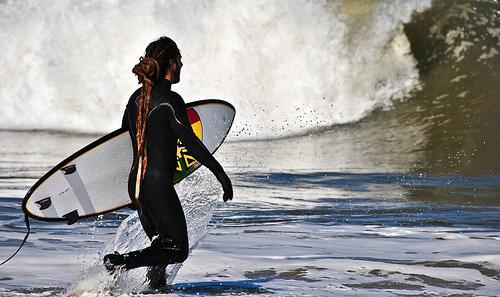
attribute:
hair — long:
[110, 22, 197, 131]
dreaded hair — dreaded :
[128, 34, 178, 86]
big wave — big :
[2, 0, 432, 144]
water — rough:
[10, 0, 480, 157]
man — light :
[102, 35, 234, 291]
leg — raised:
[105, 235, 201, 267]